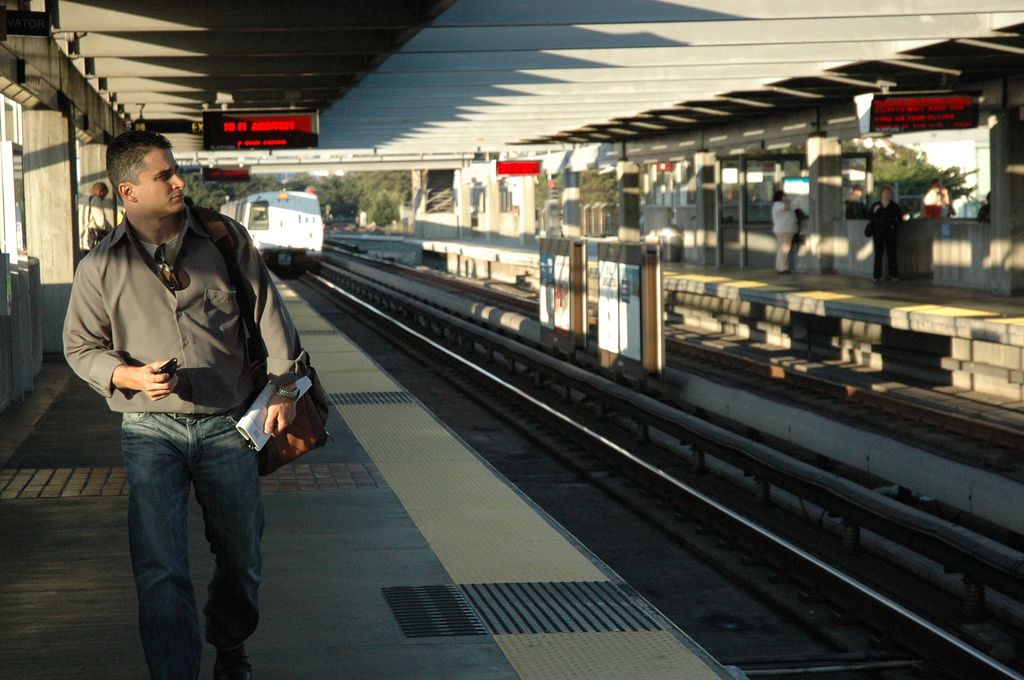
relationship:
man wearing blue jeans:
[52, 124, 321, 680] [107, 404, 284, 677]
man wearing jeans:
[52, 124, 321, 680] [112, 400, 309, 673]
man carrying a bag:
[52, 124, 321, 680] [160, 189, 349, 485]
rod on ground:
[628, 452, 895, 609] [50, 322, 500, 675]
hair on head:
[89, 124, 176, 146] [76, 117, 202, 232]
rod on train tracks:
[557, 452, 871, 595] [402, 260, 988, 624]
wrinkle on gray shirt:
[170, 269, 223, 386] [55, 200, 314, 420]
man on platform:
[52, 124, 321, 680] [0, 237, 729, 680]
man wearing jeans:
[52, 124, 321, 680] [114, 402, 344, 645]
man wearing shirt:
[52, 124, 321, 680] [47, 202, 387, 445]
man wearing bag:
[52, 124, 321, 680] [176, 171, 388, 506]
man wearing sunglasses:
[52, 124, 321, 680] [137, 242, 190, 293]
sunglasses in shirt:
[137, 242, 190, 293] [30, 204, 409, 453]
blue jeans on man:
[107, 413, 287, 660] [59, 130, 327, 530]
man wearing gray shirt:
[52, 124, 321, 680] [68, 236, 308, 442]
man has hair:
[52, 124, 321, 680] [102, 127, 173, 189]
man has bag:
[52, 124, 321, 680] [221, 359, 369, 468]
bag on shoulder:
[221, 359, 369, 468] [197, 191, 277, 308]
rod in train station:
[628, 452, 895, 609] [24, 13, 1021, 441]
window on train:
[238, 203, 280, 225] [227, 180, 336, 267]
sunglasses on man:
[137, 242, 187, 290] [85, 201, 287, 666]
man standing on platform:
[52, 124, 321, 680] [588, 167, 1021, 414]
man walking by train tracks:
[52, 124, 321, 680] [316, 230, 971, 674]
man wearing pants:
[59, 186, 297, 664] [115, 443, 291, 675]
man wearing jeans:
[52, 124, 321, 680] [102, 404, 299, 670]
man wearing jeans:
[52, 124, 321, 680] [98, 415, 269, 675]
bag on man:
[191, 202, 338, 476] [59, 148, 323, 669]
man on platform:
[52, 124, 321, 680] [318, 473, 580, 674]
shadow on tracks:
[793, 373, 880, 399] [698, 351, 992, 449]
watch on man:
[286, 365, 313, 400] [29, 142, 345, 676]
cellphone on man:
[137, 332, 196, 404] [52, 124, 321, 680]